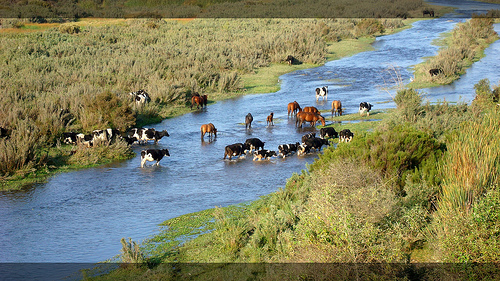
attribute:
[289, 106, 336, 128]
horse — brown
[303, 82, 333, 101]
cow — black, white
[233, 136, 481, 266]
grass — tall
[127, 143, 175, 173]
cow — black, white